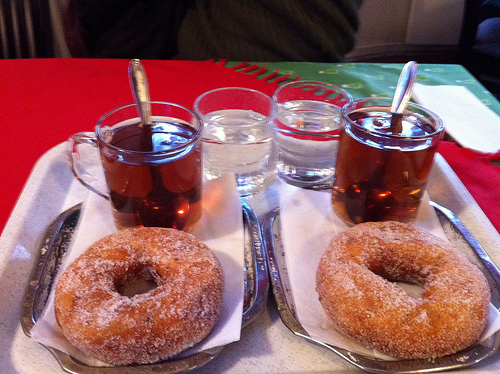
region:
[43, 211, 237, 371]
cooked doughnut on plate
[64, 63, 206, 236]
glass with silver spoon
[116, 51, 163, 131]
silver spoon handle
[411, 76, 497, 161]
white napkin laying on table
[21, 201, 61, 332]
silver serving tray covered in sugar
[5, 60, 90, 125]
red table cloth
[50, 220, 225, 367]
doughnut covered in sugar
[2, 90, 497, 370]
doughnuts with tea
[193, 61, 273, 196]
glass filled with water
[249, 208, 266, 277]
writing on side of platter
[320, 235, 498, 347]
the donuts are brown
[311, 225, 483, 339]
the donuts are icing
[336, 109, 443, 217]
the glass has red liquid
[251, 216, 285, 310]
the silvertray is mettalic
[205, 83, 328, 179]
the glasses are clear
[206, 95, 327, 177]
the liquid is water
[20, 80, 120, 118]
the clothing is red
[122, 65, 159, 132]
there is spoon in the glass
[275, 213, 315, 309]
the napkin is white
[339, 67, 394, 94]
the clothing is blue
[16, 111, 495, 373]
two identical silver trays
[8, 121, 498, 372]
two silver plates on a grey tray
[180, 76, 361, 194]
two small glasses of water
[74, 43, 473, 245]
two cups of tea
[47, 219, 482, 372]
two doughnuts on trays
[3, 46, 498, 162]
a red and green tablecloth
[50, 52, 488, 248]
two cups of tea with spoons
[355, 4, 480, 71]
a white wall in the background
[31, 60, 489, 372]
two meals that are identical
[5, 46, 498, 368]
a plastic tray on a table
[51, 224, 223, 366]
One donut with sugar.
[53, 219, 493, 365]
Two donuts with sugar.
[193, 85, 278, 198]
One glass of water.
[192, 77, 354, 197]
Two glasses of water.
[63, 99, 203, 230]
A cup of tea.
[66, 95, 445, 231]
Two cups of tea.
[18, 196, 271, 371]
A silver serving tray.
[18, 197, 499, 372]
Two silver serving tray.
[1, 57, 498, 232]
A red table cloth.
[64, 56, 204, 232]
A cup of tea with a spoon.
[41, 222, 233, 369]
a doughnut covered in sugar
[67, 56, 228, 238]
a morning beverage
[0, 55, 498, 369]
tray with food and drink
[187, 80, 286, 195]
glass with plain water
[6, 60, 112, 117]
red tablecloth under tray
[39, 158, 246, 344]
white napkin under the doughnut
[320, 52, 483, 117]
green table underneath red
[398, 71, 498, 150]
stack of napkins near the edge of the table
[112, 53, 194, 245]
spoon for stirring the drink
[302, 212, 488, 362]
doughnut on the right side of the tray